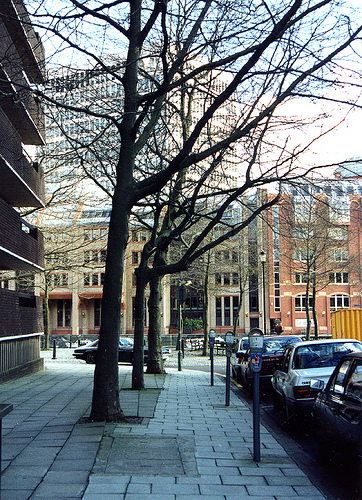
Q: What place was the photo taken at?
A: It was taken at the city.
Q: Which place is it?
A: It is a city.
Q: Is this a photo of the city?
A: Yes, it is showing the city.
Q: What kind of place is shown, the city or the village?
A: It is the city.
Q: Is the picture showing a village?
A: No, the picture is showing a city.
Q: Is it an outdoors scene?
A: Yes, it is outdoors.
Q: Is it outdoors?
A: Yes, it is outdoors.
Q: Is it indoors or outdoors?
A: It is outdoors.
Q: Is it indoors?
A: No, it is outdoors.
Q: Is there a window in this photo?
A: Yes, there are windows.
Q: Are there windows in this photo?
A: Yes, there are windows.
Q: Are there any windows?
A: Yes, there are windows.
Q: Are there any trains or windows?
A: Yes, there are windows.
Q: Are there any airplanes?
A: No, there are no airplanes.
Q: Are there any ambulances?
A: No, there are no ambulances.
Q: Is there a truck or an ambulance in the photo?
A: No, there are no ambulances or trucks.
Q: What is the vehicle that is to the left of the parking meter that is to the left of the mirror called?
A: The vehicle is a car.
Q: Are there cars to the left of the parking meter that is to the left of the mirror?
A: Yes, there is a car to the left of the meter.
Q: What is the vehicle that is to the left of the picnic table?
A: The vehicle is a car.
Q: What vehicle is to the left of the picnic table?
A: The vehicle is a car.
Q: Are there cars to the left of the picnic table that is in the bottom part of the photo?
A: Yes, there is a car to the left of the picnic table.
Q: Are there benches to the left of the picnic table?
A: No, there is a car to the left of the picnic table.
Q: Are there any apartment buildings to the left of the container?
A: Yes, there is an apartment building to the left of the container.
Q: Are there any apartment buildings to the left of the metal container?
A: Yes, there is an apartment building to the left of the container.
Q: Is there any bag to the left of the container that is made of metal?
A: No, there is an apartment building to the left of the container.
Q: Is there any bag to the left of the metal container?
A: No, there is an apartment building to the left of the container.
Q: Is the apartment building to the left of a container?
A: Yes, the apartment building is to the left of a container.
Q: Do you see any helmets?
A: No, there are no helmets.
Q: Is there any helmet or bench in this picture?
A: No, there are no helmets or benches.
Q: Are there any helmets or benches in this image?
A: No, there are no helmets or benches.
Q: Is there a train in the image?
A: No, there are no trains.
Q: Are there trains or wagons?
A: No, there are no trains or wagons.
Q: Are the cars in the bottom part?
A: Yes, the cars are in the bottom of the image.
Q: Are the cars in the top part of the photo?
A: No, the cars are in the bottom of the image.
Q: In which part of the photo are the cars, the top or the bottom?
A: The cars are in the bottom of the image.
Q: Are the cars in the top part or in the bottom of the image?
A: The cars are in the bottom of the image.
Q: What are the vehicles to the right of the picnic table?
A: The vehicles are cars.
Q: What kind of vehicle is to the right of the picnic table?
A: The vehicles are cars.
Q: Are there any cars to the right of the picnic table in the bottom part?
A: Yes, there are cars to the right of the picnic table.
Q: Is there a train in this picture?
A: No, there are no trains.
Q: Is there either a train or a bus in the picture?
A: No, there are no trains or buses.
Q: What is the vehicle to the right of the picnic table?
A: The vehicle is a car.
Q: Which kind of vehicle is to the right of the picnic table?
A: The vehicle is a car.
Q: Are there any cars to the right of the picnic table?
A: Yes, there is a car to the right of the picnic table.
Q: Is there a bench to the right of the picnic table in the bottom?
A: No, there is a car to the right of the picnic table.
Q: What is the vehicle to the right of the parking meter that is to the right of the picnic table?
A: The vehicle is a car.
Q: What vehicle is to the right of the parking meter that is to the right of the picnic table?
A: The vehicle is a car.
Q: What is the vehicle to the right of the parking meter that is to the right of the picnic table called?
A: The vehicle is a car.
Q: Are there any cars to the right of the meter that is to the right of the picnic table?
A: Yes, there is a car to the right of the meter.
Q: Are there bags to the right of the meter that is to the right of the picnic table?
A: No, there is a car to the right of the parking meter.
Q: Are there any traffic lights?
A: No, there are no traffic lights.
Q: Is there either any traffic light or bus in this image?
A: No, there are no traffic lights or buses.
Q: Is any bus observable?
A: No, there are no buses.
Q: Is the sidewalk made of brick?
A: Yes, the sidewalk is made of brick.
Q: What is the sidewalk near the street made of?
A: The sidewalk is made of brick.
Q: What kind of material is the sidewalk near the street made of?
A: The sidewalk is made of brick.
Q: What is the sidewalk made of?
A: The sidewalk is made of brick.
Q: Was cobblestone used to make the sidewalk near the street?
A: No, the sidewalk is made of brick.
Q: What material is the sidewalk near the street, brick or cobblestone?
A: The sidewalk is made of brick.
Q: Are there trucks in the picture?
A: No, there are no trucks.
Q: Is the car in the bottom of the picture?
A: Yes, the car is in the bottom of the image.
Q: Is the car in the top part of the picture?
A: No, the car is in the bottom of the image.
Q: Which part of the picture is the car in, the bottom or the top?
A: The car is in the bottom of the image.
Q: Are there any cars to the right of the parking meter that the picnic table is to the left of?
A: Yes, there is a car to the right of the parking meter.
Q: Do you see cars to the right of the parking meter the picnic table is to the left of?
A: Yes, there is a car to the right of the parking meter.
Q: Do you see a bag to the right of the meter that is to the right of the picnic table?
A: No, there is a car to the right of the meter.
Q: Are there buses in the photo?
A: No, there are no buses.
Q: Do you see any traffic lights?
A: No, there are no traffic lights.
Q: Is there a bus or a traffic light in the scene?
A: No, there are no traffic lights or buses.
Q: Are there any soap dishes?
A: No, there are no soap dishes.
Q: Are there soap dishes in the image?
A: No, there are no soap dishes.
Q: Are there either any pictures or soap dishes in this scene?
A: No, there are no soap dishes or pictures.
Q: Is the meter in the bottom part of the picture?
A: Yes, the meter is in the bottom of the image.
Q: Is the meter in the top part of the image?
A: No, the meter is in the bottom of the image.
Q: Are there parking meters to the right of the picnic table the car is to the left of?
A: Yes, there is a parking meter to the right of the picnic table.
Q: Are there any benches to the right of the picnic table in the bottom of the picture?
A: No, there is a parking meter to the right of the picnic table.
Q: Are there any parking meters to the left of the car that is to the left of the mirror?
A: Yes, there is a parking meter to the left of the car.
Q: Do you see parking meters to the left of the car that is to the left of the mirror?
A: Yes, there is a parking meter to the left of the car.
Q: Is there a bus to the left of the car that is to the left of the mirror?
A: No, there is a parking meter to the left of the car.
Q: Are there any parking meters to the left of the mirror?
A: Yes, there is a parking meter to the left of the mirror.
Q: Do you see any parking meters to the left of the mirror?
A: Yes, there is a parking meter to the left of the mirror.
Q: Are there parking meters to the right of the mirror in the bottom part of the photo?
A: No, the parking meter is to the left of the mirror.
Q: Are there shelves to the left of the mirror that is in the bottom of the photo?
A: No, there is a parking meter to the left of the mirror.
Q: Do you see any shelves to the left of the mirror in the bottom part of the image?
A: No, there is a parking meter to the left of the mirror.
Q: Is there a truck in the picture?
A: No, there are no trucks.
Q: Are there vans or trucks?
A: No, there are no trucks or vans.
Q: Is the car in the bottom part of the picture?
A: Yes, the car is in the bottom of the image.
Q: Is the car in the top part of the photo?
A: No, the car is in the bottom of the image.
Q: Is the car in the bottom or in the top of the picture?
A: The car is in the bottom of the image.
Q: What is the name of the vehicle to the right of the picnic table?
A: The vehicle is a car.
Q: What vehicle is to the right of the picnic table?
A: The vehicle is a car.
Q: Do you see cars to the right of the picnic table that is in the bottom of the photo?
A: Yes, there is a car to the right of the picnic table.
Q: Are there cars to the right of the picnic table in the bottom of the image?
A: Yes, there is a car to the right of the picnic table.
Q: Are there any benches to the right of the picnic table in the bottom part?
A: No, there is a car to the right of the picnic table.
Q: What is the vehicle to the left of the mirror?
A: The vehicle is a car.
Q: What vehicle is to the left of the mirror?
A: The vehicle is a car.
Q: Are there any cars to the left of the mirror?
A: Yes, there is a car to the left of the mirror.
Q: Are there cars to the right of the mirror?
A: No, the car is to the left of the mirror.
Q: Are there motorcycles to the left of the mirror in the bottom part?
A: No, there is a car to the left of the mirror.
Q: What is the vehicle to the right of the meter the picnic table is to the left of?
A: The vehicle is a car.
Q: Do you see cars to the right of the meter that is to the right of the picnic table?
A: Yes, there is a car to the right of the meter.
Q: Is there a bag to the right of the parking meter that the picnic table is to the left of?
A: No, there is a car to the right of the parking meter.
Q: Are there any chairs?
A: No, there are no chairs.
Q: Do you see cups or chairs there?
A: No, there are no chairs or cups.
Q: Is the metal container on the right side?
A: Yes, the container is on the right of the image.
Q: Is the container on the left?
A: No, the container is on the right of the image.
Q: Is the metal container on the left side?
A: No, the container is on the right of the image.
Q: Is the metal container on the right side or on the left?
A: The container is on the right of the image.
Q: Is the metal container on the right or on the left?
A: The container is on the right of the image.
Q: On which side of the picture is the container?
A: The container is on the right of the image.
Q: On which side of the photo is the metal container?
A: The container is on the right of the image.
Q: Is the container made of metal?
A: Yes, the container is made of metal.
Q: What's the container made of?
A: The container is made of metal.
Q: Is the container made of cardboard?
A: No, the container is made of metal.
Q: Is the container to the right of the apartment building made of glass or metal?
A: The container is made of metal.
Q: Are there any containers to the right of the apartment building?
A: Yes, there is a container to the right of the apartment building.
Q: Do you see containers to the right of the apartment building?
A: Yes, there is a container to the right of the apartment building.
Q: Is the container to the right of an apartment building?
A: Yes, the container is to the right of an apartment building.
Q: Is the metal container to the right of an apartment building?
A: Yes, the container is to the right of an apartment building.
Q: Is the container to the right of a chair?
A: No, the container is to the right of an apartment building.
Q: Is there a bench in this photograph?
A: No, there are no benches.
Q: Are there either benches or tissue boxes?
A: No, there are no benches or tissue boxes.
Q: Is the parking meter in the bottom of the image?
A: Yes, the parking meter is in the bottom of the image.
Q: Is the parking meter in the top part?
A: No, the parking meter is in the bottom of the image.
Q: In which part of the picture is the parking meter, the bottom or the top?
A: The parking meter is in the bottom of the image.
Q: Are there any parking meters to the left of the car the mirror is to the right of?
A: Yes, there is a parking meter to the left of the car.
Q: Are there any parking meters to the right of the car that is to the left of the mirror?
A: No, the parking meter is to the left of the car.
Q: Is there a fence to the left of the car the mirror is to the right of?
A: No, there is a parking meter to the left of the car.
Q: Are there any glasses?
A: No, there are no glasses.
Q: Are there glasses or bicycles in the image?
A: No, there are no glasses or bicycles.